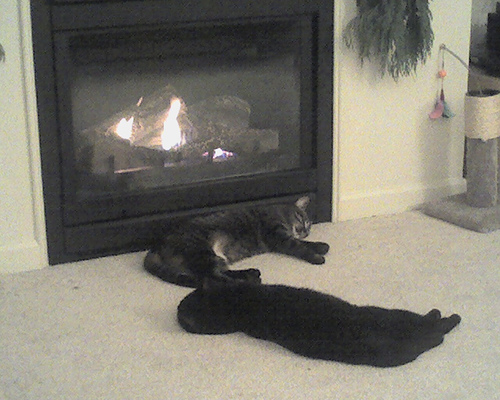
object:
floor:
[3, 273, 498, 398]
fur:
[176, 277, 460, 367]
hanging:
[338, 0, 434, 81]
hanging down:
[424, 42, 459, 123]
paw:
[314, 241, 330, 255]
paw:
[247, 268, 261, 278]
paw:
[451, 312, 462, 330]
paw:
[427, 308, 441, 318]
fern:
[337, 0, 437, 82]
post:
[424, 88, 498, 232]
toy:
[431, 44, 456, 126]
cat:
[176, 272, 460, 367]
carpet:
[0, 190, 497, 398]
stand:
[421, 79, 498, 233]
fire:
[101, 72, 240, 175]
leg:
[279, 241, 310, 260]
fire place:
[68, 79, 279, 185]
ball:
[438, 69, 446, 78]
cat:
[143, 189, 331, 288]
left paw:
[307, 250, 326, 265]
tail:
[143, 251, 202, 289]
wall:
[333, 0, 478, 222]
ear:
[295, 194, 310, 208]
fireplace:
[55, 22, 314, 227]